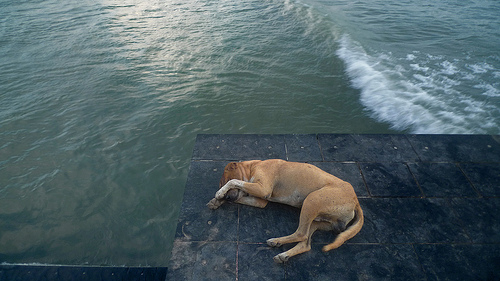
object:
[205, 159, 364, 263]
dog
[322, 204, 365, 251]
tail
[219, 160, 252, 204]
head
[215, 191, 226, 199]
paw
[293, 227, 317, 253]
leg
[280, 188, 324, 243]
leg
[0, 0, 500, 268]
ocean waves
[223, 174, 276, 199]
legs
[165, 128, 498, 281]
platform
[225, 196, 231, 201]
nose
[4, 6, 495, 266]
water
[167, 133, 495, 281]
ground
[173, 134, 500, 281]
stone